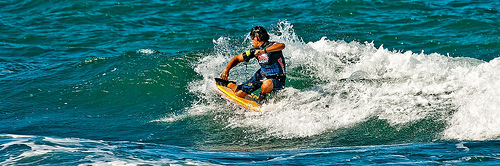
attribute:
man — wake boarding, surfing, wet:
[245, 23, 284, 85]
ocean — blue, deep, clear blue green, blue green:
[9, 8, 490, 165]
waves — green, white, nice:
[29, 52, 162, 122]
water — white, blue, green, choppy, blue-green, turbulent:
[316, 27, 499, 139]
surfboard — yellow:
[209, 71, 255, 123]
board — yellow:
[213, 80, 257, 119]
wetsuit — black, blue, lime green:
[251, 46, 282, 84]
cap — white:
[371, 46, 400, 67]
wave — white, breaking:
[296, 22, 473, 111]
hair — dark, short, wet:
[243, 22, 272, 39]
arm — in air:
[254, 39, 302, 72]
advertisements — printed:
[255, 53, 272, 72]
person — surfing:
[247, 21, 298, 92]